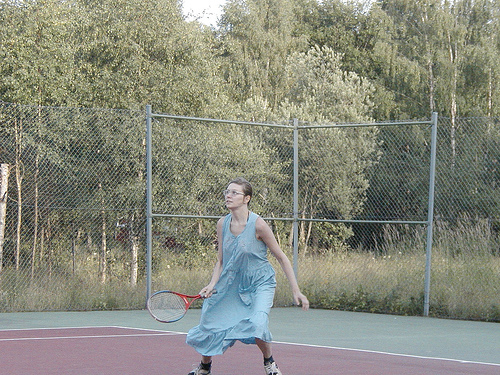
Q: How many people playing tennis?
A: One.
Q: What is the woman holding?
A: A racket.